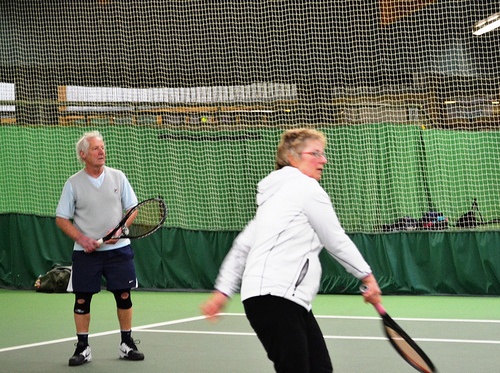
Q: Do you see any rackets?
A: Yes, there is a racket.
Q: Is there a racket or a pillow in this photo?
A: Yes, there is a racket.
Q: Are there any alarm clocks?
A: No, there are no alarm clocks.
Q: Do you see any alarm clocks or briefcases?
A: No, there are no alarm clocks or briefcases.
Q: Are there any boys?
A: No, there are no boys.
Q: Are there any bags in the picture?
A: Yes, there is a bag.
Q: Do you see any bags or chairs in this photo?
A: Yes, there is a bag.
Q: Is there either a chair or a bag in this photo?
A: Yes, there is a bag.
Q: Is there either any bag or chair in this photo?
A: Yes, there is a bag.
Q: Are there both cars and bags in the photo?
A: No, there is a bag but no cars.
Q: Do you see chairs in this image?
A: No, there are no chairs.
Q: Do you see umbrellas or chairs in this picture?
A: No, there are no chairs or umbrellas.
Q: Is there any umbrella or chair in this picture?
A: No, there are no chairs or umbrellas.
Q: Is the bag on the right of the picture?
A: No, the bag is on the left of the image.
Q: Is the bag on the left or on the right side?
A: The bag is on the left of the image.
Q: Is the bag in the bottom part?
A: Yes, the bag is in the bottom of the image.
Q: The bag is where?
A: The bag is on the floor.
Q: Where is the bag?
A: The bag is on the floor.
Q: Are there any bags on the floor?
A: Yes, there is a bag on the floor.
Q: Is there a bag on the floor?
A: Yes, there is a bag on the floor.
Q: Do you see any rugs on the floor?
A: No, there is a bag on the floor.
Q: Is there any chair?
A: No, there are no chairs.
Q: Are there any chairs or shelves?
A: No, there are no chairs or shelves.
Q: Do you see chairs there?
A: No, there are no chairs.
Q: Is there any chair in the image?
A: No, there are no chairs.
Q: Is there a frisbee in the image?
A: No, there are no frisbees.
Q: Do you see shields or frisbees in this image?
A: No, there are no frisbees or shields.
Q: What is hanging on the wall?
A: The net is hanging on the wall.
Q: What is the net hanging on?
A: The net is hanging on the wall.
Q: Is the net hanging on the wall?
A: Yes, the net is hanging on the wall.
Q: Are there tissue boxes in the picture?
A: No, there are no tissue boxes.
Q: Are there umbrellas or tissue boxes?
A: No, there are no tissue boxes or umbrellas.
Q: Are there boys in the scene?
A: No, there are no boys.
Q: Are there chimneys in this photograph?
A: No, there are no chimneys.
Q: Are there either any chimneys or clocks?
A: No, there are no chimneys or clocks.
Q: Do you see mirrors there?
A: No, there are no mirrors.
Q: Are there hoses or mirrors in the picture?
A: No, there are no mirrors or hoses.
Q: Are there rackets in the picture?
A: Yes, there is a racket.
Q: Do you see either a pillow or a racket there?
A: Yes, there is a racket.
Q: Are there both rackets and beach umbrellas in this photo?
A: No, there is a racket but no beach umbrellas.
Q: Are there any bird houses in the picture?
A: No, there are no bird houses.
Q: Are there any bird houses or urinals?
A: No, there are no bird houses or urinals.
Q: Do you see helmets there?
A: No, there are no helmets.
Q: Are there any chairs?
A: No, there are no chairs.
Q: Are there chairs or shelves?
A: No, there are no chairs or shelves.